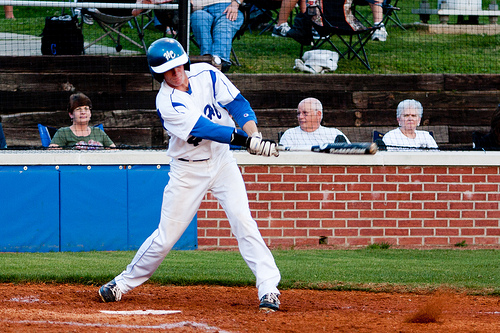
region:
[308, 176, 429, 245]
red brick wall with light gray cement grout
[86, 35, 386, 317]
batter swing bat on home base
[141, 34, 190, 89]
blue metallic helmet on batter's head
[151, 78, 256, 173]
royal blue and white uniform shit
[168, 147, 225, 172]
dark belt in white pants around waiste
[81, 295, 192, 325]
white home base in orange dirt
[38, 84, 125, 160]
woman with brown hair and green shirt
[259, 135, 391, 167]
blue and silver painted metal bat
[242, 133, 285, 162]
white and black gloves on hands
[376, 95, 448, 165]
woman with white hair and white shirt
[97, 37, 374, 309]
a young baseball player swinging bat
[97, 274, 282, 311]
blue and white baseball cleats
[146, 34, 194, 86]
a hard blue baseball helmet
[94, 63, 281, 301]
white and blue baseball uniform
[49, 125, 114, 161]
a green short sleeve shirt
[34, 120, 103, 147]
a blue fabric folding chair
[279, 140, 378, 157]
a dark baseball bat with white handle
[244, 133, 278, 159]
a pair of thin white baseball gloves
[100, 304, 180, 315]
home plate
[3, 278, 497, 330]
dirt from a baseball diamond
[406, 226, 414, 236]
part of a wall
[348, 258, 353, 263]
part of a lawn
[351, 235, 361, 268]
part of a field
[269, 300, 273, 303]
part of a shoe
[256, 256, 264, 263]
part of a trouser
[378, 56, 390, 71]
part of a fence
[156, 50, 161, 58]
part of an helmet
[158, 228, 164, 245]
part of a trouser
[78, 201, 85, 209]
part of a board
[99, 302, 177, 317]
Home plate beneath the batter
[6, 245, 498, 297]
Green grass on the field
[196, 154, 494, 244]
A brick wall behind the batter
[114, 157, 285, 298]
The batter is wearing white pants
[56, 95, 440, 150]
Spectators behind the batter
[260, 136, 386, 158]
The man is holding a bat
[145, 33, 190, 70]
The man is wearing a helmet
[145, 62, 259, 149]
The man is wearing a blue and white jersey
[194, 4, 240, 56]
This person is wearing blue jeans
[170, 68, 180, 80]
The nose of the batter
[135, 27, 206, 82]
blue and white batter's helmet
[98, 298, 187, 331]
white homeplate base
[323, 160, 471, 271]
red brick wall behind batter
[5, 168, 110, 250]
blue padded wall behind batter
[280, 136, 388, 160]
blue and white bat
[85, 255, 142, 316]
man's right tilted foot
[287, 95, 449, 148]
spectator's in background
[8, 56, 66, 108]
brown wooden wall on left of photo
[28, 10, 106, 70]
black bag with blue piece in upper left of photo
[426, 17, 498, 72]
black metal fencing